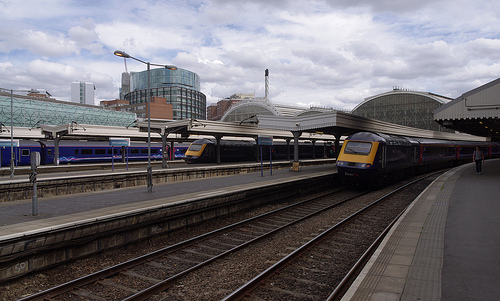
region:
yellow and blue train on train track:
[325, 126, 499, 192]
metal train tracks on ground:
[13, 163, 454, 299]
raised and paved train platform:
[338, 153, 498, 299]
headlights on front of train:
[331, 157, 375, 171]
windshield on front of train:
[341, 136, 374, 157]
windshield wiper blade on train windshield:
[343, 143, 360, 154]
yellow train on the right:
[333, 135, 490, 180]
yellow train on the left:
[179, 138, 494, 174]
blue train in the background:
[3, 136, 185, 163]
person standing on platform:
[472, 142, 484, 172]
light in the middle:
[111, 50, 176, 169]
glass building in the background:
[119, 66, 207, 126]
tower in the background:
[262, 65, 269, 106]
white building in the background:
[70, 79, 97, 106]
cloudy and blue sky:
[1, 2, 498, 109]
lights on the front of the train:
[330, 138, 497, 178]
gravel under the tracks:
[179, 214, 347, 298]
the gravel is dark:
[174, 232, 319, 298]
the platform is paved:
[442, 185, 497, 295]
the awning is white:
[450, 86, 497, 123]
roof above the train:
[320, 107, 482, 168]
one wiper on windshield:
[346, 139, 372, 160]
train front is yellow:
[340, 139, 379, 160]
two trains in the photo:
[187, 136, 457, 181]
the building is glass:
[130, 66, 207, 122]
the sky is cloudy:
[166, 14, 469, 74]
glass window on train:
[345, 140, 371, 155]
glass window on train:
[188, 142, 202, 149]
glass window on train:
[21, 146, 31, 156]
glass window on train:
[73, 148, 78, 154]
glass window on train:
[81, 147, 95, 153]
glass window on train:
[93, 148, 106, 154]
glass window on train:
[106, 146, 116, 153]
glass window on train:
[117, 148, 126, 154]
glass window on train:
[127, 148, 142, 155]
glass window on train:
[140, 147, 151, 153]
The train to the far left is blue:
[6, 132, 186, 169]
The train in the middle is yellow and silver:
[179, 135, 331, 159]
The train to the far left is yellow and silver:
[321, 121, 498, 168]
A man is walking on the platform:
[458, 140, 498, 178]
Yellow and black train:
[333, 125, 498, 182]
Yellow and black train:
[174, 134, 345, 165]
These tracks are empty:
[153, 240, 391, 285]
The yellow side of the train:
[281, 118, 423, 195]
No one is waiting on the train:
[350, 146, 489, 298]